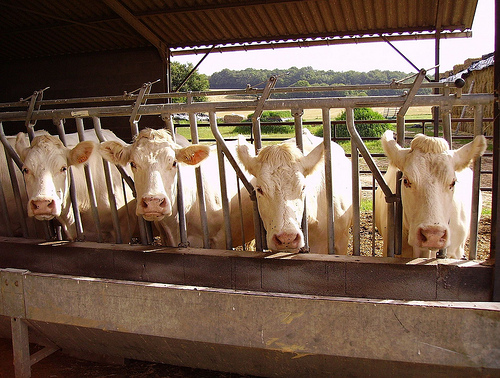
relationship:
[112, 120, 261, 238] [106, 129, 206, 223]
cow has head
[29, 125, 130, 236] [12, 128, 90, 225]
cow has head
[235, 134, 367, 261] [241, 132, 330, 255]
cow has head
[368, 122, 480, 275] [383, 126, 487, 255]
cow has head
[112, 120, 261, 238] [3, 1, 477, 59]
cow under roof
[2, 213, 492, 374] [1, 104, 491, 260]
trough has holes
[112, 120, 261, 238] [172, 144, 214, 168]
cow has ear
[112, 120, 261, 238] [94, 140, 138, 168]
cow has ear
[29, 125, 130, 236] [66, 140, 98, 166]
cow has ear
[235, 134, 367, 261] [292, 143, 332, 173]
cow has ear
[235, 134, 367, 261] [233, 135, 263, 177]
cow has ear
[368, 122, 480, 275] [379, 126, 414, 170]
cow has ear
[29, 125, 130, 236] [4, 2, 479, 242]
cow in barn